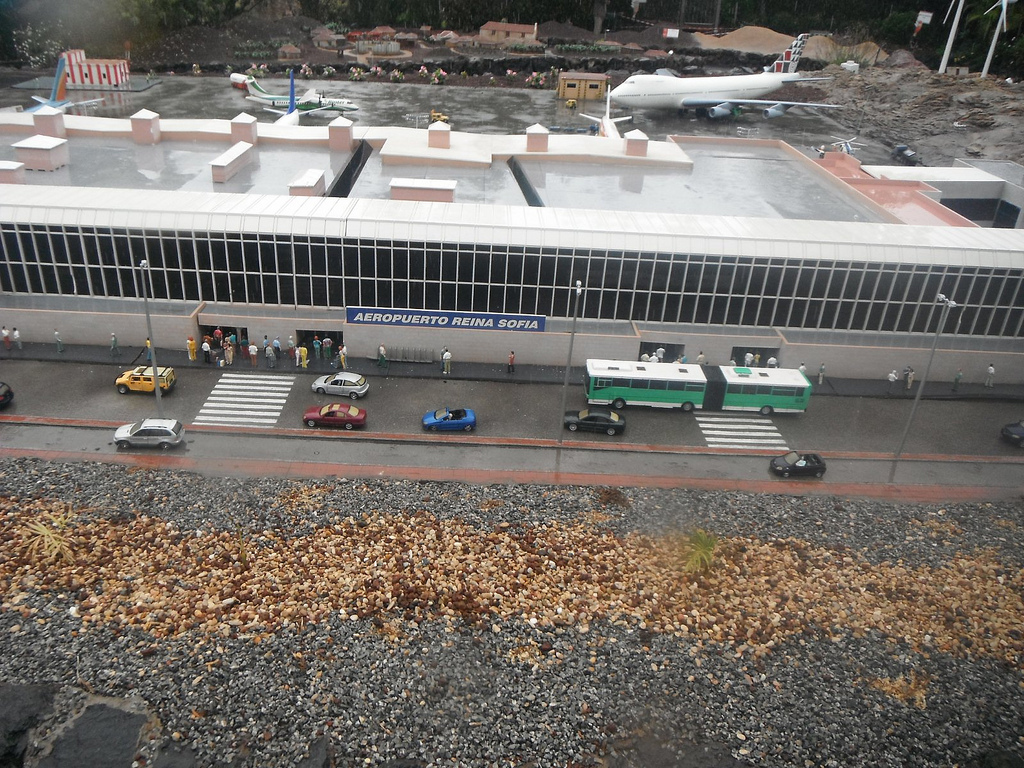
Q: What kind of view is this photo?
A: Aerial.